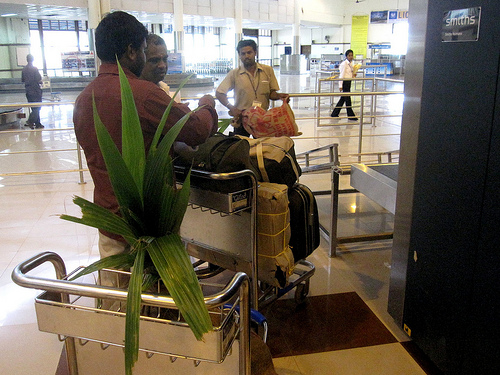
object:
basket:
[61, 265, 228, 326]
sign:
[439, 8, 480, 43]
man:
[329, 49, 361, 121]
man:
[20, 52, 45, 130]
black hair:
[236, 39, 256, 51]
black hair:
[345, 49, 353, 56]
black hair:
[94, 9, 147, 60]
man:
[215, 40, 290, 138]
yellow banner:
[350, 16, 370, 58]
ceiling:
[116, 1, 407, 20]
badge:
[252, 100, 263, 108]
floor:
[18, 177, 68, 242]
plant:
[50, 53, 218, 374]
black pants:
[331, 80, 356, 116]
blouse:
[338, 59, 354, 88]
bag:
[228, 95, 303, 139]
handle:
[248, 312, 271, 344]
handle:
[10, 252, 250, 311]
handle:
[171, 164, 257, 190]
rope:
[258, 211, 287, 216]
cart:
[171, 164, 315, 313]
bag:
[193, 134, 262, 182]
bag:
[233, 134, 303, 188]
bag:
[256, 182, 295, 289]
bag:
[285, 182, 321, 264]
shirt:
[72, 65, 218, 243]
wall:
[386, 0, 498, 373]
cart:
[11, 251, 252, 374]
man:
[71, 11, 218, 310]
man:
[140, 34, 190, 108]